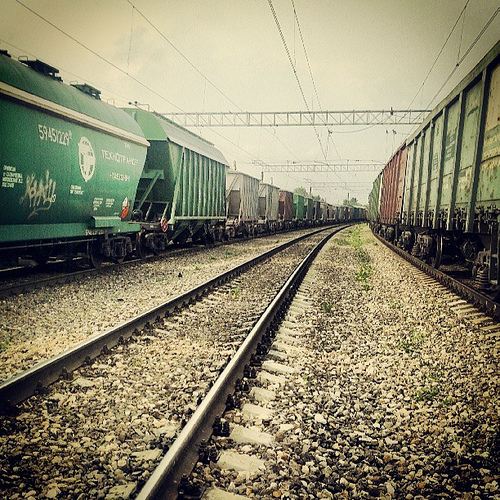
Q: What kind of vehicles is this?
A: Train.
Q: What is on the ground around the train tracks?
A: Gravel.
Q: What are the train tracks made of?
A: Metal.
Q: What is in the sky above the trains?
A: Power lines.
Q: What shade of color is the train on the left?
A: Green.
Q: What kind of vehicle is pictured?
A: Trains.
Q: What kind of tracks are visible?
A: Train tracks.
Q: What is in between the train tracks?
A: Gravel.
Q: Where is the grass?
A: In between the gravel.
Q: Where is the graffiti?
A: On the left train's front green car.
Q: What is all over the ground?
A: Gravel.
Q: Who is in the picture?
A: No one.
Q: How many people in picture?
A: None.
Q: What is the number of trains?
A: Two.